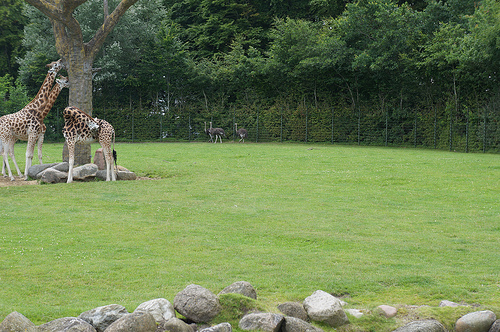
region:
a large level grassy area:
[91, 160, 478, 281]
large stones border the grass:
[22, 285, 477, 320]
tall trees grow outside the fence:
[62, 16, 482, 148]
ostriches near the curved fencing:
[110, 96, 490, 151]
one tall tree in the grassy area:
[40, 21, 126, 186]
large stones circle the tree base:
[32, 146, 153, 192]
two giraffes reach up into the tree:
[20, 37, 65, 182]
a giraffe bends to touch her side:
[57, 97, 133, 187]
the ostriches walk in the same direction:
[192, 100, 262, 150]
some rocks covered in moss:
[196, 285, 473, 326]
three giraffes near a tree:
[0, 53, 128, 183]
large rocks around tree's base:
[26, 157, 134, 187]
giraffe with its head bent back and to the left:
[60, 104, 106, 139]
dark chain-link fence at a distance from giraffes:
[85, 114, 499, 150]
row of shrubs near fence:
[31, 105, 498, 154]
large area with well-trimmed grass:
[0, 142, 497, 299]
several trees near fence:
[1, 0, 495, 105]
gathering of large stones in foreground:
[3, 279, 498, 329]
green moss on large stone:
[216, 294, 255, 318]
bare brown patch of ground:
[0, 171, 33, 188]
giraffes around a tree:
[0, 47, 133, 199]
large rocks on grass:
[0, 277, 387, 329]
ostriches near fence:
[197, 116, 254, 153]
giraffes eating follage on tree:
[30, 53, 78, 101]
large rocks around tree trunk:
[25, 143, 136, 193]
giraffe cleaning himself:
[55, 105, 128, 193]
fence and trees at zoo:
[326, 13, 493, 184]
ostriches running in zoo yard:
[172, 100, 272, 160]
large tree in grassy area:
[20, 0, 153, 186]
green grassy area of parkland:
[185, 153, 450, 275]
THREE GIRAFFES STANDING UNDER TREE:
[0, 52, 124, 200]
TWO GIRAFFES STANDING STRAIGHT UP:
[0, 51, 77, 186]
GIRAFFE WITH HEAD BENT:
[58, 100, 145, 193]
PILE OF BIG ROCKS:
[27, 277, 498, 329]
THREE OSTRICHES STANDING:
[197, 115, 254, 147]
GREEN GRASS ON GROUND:
[0, 149, 499, 278]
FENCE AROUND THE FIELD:
[109, 5, 499, 152]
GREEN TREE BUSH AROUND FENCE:
[125, 103, 499, 146]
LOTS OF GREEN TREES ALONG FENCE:
[110, 0, 498, 95]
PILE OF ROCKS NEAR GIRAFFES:
[26, 154, 139, 189]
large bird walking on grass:
[199, 111, 233, 153]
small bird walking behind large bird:
[231, 114, 263, 151]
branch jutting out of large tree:
[85, 53, 115, 80]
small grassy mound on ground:
[220, 287, 261, 312]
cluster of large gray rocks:
[83, 280, 224, 327]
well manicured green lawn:
[178, 184, 475, 241]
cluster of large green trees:
[193, 20, 484, 69]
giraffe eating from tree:
[36, 56, 80, 78]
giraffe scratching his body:
[60, 102, 126, 185]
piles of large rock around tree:
[31, 150, 168, 207]